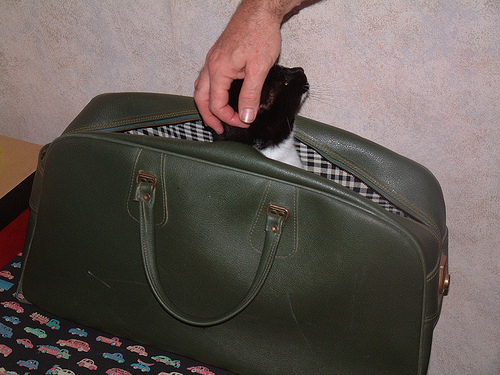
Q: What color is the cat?
A: Black.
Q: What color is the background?
A: Pink.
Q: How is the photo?
A: Clear.